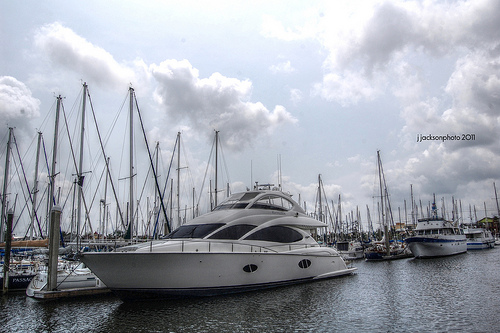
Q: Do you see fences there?
A: No, there are no fences.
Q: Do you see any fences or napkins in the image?
A: No, there are no fences or napkins.